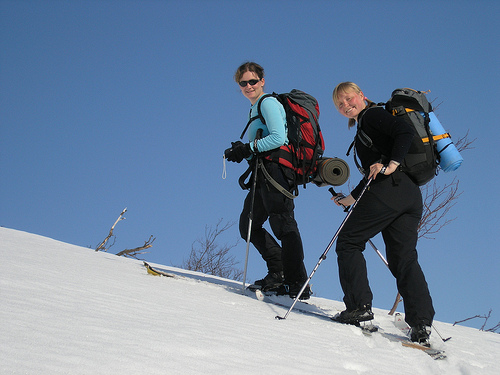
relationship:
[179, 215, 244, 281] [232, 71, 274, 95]
bare branch wearing sunglasses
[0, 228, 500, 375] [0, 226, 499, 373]
ground on ground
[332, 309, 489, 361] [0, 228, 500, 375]
tracks in ground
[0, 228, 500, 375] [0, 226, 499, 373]
ground covering ground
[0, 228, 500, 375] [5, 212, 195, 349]
ground covering ground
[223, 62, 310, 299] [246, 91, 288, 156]
skiers wearing shirt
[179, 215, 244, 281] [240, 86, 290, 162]
bare branch wearing shirt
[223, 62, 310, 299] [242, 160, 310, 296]
skiers wearing pants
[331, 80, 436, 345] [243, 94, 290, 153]
lady wearing shirt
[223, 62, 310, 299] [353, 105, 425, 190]
skiers wearing shirt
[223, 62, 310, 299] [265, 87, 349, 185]
skiers wearing backpack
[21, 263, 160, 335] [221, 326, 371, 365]
ground covered in snow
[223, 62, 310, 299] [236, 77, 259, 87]
skiers wearing sunglasses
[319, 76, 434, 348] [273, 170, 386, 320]
woman holding pole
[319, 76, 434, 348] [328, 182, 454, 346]
woman holding pole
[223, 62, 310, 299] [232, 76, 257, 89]
skiers wearing sunglasses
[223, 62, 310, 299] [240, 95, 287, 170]
skiers wearing shirt